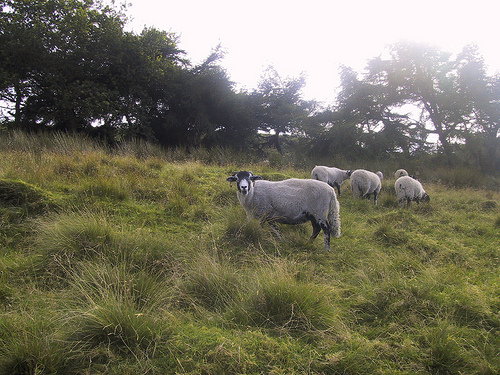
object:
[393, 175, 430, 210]
sheep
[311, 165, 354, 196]
sheep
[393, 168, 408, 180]
sheep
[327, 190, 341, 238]
tail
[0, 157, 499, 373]
land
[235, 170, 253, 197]
face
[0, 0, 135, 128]
trees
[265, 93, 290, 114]
leaves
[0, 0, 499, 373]
field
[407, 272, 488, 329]
grass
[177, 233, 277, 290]
grass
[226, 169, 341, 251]
sheep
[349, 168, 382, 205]
sheep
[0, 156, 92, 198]
grass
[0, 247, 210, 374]
weeds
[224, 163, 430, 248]
herd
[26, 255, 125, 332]
grass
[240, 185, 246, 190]
snout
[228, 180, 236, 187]
ear tag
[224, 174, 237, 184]
ear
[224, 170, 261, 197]
head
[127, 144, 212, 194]
grass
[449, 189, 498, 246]
grass